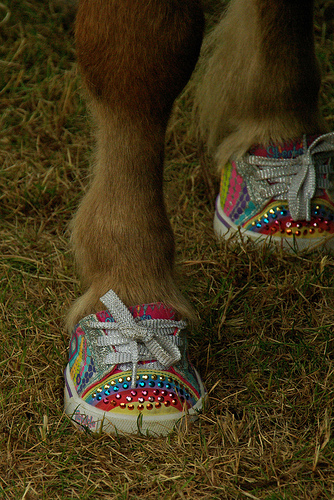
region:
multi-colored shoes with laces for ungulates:
[62, 298, 211, 435]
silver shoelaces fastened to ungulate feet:
[89, 290, 186, 380]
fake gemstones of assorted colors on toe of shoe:
[92, 375, 192, 409]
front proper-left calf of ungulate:
[75, 104, 174, 276]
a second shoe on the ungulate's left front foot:
[210, 133, 332, 247]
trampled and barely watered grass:
[0, 441, 330, 497]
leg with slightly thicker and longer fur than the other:
[208, 0, 320, 156]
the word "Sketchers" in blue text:
[265, 145, 304, 160]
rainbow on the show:
[87, 354, 197, 432]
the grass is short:
[167, 462, 238, 493]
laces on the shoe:
[87, 300, 173, 367]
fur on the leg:
[109, 195, 152, 270]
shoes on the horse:
[87, 115, 301, 430]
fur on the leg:
[211, 10, 285, 141]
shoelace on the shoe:
[255, 135, 312, 223]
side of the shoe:
[211, 154, 240, 224]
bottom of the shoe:
[82, 413, 160, 442]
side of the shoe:
[258, 236, 303, 247]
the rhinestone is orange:
[127, 402, 134, 412]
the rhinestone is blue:
[138, 378, 146, 388]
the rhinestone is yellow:
[152, 371, 157, 380]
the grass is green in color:
[279, 337, 301, 363]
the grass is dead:
[249, 442, 270, 456]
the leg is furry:
[103, 243, 133, 279]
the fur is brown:
[120, 30, 140, 60]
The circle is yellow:
[87, 388, 97, 399]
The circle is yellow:
[93, 384, 104, 394]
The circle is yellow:
[99, 379, 110, 393]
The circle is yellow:
[109, 376, 116, 386]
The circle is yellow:
[114, 374, 129, 383]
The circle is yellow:
[126, 371, 134, 383]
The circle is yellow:
[132, 370, 139, 381]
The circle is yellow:
[140, 370, 149, 380]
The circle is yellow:
[150, 368, 158, 381]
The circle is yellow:
[158, 369, 166, 382]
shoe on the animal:
[44, 295, 220, 448]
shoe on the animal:
[39, 309, 220, 439]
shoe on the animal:
[66, 315, 221, 469]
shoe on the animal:
[54, 309, 206, 478]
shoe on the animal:
[59, 308, 225, 459]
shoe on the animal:
[49, 310, 205, 442]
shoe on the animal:
[48, 322, 207, 440]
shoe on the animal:
[56, 320, 203, 442]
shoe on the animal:
[48, 313, 202, 436]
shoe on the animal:
[53, 333, 190, 447]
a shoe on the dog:
[50, 260, 226, 496]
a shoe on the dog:
[49, 270, 205, 440]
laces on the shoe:
[95, 292, 181, 391]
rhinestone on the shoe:
[152, 398, 160, 407]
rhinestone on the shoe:
[139, 401, 147, 407]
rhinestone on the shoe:
[123, 397, 133, 404]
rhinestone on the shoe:
[116, 400, 120, 402]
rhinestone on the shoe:
[172, 377, 181, 389]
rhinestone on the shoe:
[135, 371, 154, 385]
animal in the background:
[21, 8, 318, 426]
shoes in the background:
[37, 141, 320, 445]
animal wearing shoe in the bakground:
[45, 136, 331, 470]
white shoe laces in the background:
[78, 287, 241, 434]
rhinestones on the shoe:
[53, 282, 272, 467]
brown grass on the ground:
[25, 190, 313, 496]